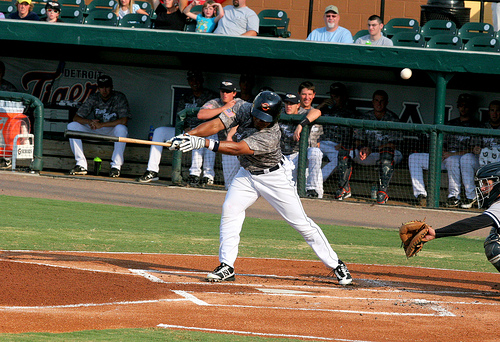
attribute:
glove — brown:
[398, 211, 429, 258]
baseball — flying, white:
[396, 61, 416, 81]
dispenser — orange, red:
[2, 99, 28, 161]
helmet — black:
[249, 88, 284, 130]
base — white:
[126, 261, 459, 321]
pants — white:
[215, 163, 342, 272]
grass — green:
[4, 199, 210, 256]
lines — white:
[24, 256, 477, 328]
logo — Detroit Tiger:
[5, 59, 90, 108]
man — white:
[336, 90, 408, 201]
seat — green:
[464, 29, 496, 50]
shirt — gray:
[222, 98, 286, 175]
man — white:
[298, 1, 356, 46]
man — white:
[353, 14, 402, 50]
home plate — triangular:
[253, 284, 320, 298]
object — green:
[90, 153, 103, 172]